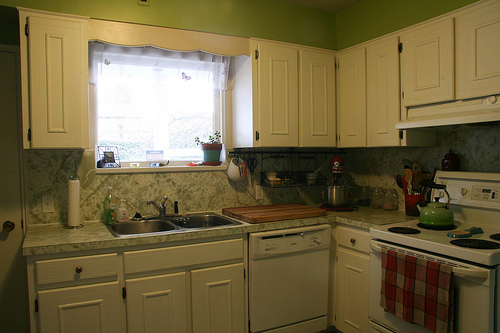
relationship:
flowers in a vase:
[192, 130, 223, 143] [198, 142, 226, 164]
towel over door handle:
[379, 240, 451, 330] [368, 239, 484, 281]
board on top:
[231, 198, 336, 226] [334, 202, 404, 232]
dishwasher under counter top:
[247, 223, 330, 333] [256, 200, 318, 242]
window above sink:
[86, 43, 226, 163] [102, 205, 236, 239]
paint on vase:
[205, 150, 219, 165] [200, 141, 223, 166]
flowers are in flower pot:
[198, 132, 221, 141] [200, 141, 226, 167]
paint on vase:
[202, 143, 222, 149] [200, 141, 223, 166]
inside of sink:
[124, 220, 162, 230] [110, 217, 172, 235]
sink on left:
[110, 217, 172, 235] [112, 214, 177, 234]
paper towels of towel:
[66, 178, 81, 228] [70, 186, 76, 222]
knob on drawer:
[72, 261, 86, 278] [32, 250, 122, 286]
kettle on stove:
[413, 183, 454, 227] [367, 167, 481, 323]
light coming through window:
[107, 62, 219, 153] [90, 51, 220, 157]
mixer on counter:
[319, 155, 352, 208] [222, 204, 402, 223]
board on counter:
[220, 203, 327, 225] [220, 209, 418, 230]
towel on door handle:
[377, 248, 449, 332] [368, 239, 488, 279]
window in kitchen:
[86, 43, 226, 167] [5, 7, 484, 323]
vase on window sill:
[200, 140, 223, 166] [94, 166, 230, 174]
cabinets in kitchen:
[247, 10, 482, 147] [5, 7, 484, 323]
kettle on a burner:
[413, 183, 454, 227] [414, 219, 459, 233]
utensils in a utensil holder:
[396, 167, 413, 197] [403, 191, 421, 216]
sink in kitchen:
[110, 217, 172, 237] [5, 7, 484, 323]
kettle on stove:
[410, 180, 455, 234] [370, 165, 499, 332]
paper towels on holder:
[69, 174, 87, 223] [65, 173, 81, 231]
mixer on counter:
[312, 153, 353, 218] [232, 200, 399, 236]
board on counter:
[220, 203, 327, 225] [214, 204, 404, 234]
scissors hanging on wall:
[244, 149, 263, 197] [7, 160, 356, 219]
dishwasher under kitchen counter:
[250, 221, 331, 331] [20, 195, 420, 256]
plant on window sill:
[195, 130, 224, 168] [100, 165, 230, 180]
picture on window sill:
[99, 148, 120, 175] [94, 161, 227, 169]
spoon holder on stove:
[444, 225, 486, 245] [370, 165, 499, 332]